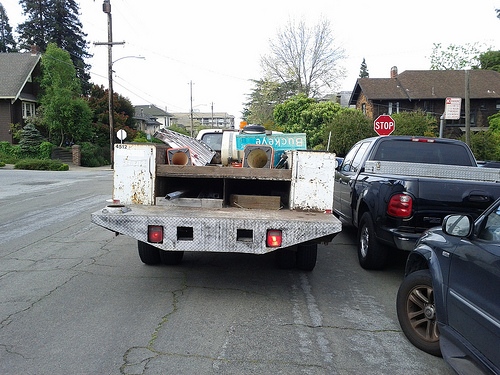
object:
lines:
[297, 271, 334, 362]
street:
[10, 172, 414, 367]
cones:
[170, 151, 190, 165]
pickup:
[333, 134, 499, 268]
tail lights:
[147, 223, 166, 243]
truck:
[90, 125, 345, 272]